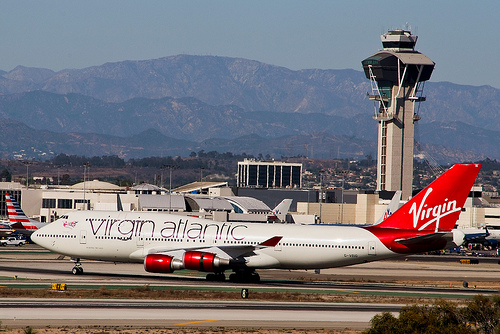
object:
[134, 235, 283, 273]
wing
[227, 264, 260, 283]
wheels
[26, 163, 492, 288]
plane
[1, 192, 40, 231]
design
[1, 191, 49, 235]
plane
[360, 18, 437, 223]
tower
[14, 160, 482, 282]
planes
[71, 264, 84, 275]
wheels